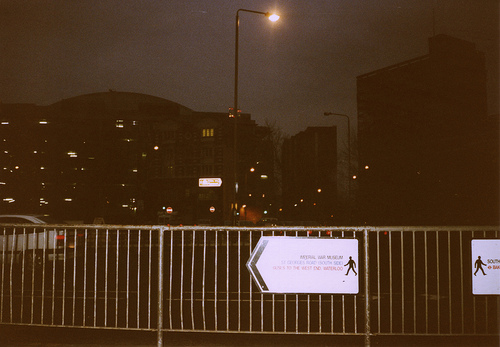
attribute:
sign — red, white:
[193, 175, 227, 190]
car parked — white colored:
[7, 201, 65, 264]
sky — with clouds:
[4, 3, 498, 223]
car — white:
[7, 202, 79, 283]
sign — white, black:
[244, 238, 360, 295]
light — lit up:
[223, 2, 286, 205]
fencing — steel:
[4, 210, 492, 340]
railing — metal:
[42, 221, 308, 316]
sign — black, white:
[469, 235, 499, 295]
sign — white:
[224, 225, 391, 312]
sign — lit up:
[193, 173, 227, 188]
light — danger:
[55, 237, 65, 244]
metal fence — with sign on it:
[43, 213, 413, 319]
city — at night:
[3, 4, 499, 231]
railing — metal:
[2, 220, 499, 337]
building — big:
[351, 34, 496, 223]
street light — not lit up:
[323, 107, 353, 213]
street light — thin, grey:
[197, 2, 319, 238]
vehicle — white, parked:
[3, 199, 82, 286]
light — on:
[37, 120, 47, 125]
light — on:
[151, 144, 158, 150]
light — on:
[248, 165, 256, 172]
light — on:
[291, 202, 297, 205]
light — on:
[361, 163, 369, 170]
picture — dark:
[1, 1, 483, 343]